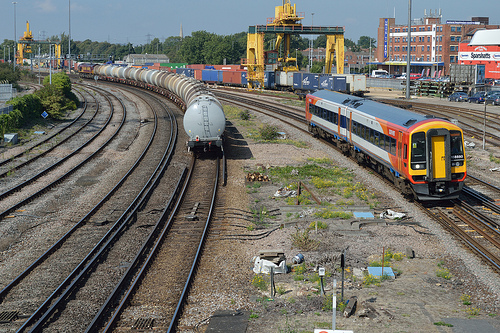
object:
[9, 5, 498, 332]
railroad station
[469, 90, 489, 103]
cars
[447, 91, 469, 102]
car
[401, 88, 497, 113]
street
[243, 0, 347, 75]
crane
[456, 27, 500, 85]
building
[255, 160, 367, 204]
grass patch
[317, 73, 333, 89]
freight car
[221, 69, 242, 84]
freight car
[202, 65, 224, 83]
freight car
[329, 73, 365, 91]
freight car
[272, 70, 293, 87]
freight car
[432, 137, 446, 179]
door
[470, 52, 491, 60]
words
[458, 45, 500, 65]
sign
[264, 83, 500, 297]
railroad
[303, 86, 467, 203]
passenger train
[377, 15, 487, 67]
brick building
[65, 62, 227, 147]
tanker cars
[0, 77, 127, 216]
tracks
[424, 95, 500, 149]
tracks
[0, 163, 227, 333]
tracks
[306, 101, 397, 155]
row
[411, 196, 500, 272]
tracks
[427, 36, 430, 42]
windows